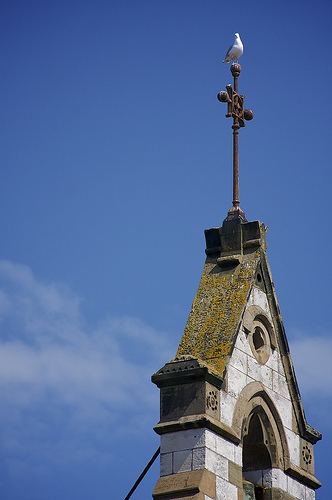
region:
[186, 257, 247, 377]
Moss covering the roof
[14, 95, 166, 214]
A cloudless blue sky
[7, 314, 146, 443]
Thin white clouds in the sky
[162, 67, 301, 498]
An old stone building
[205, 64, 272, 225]
A weather vane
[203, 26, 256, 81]
Bird on the weather vane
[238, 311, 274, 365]
Open window on the buillding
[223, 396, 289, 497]
A small archway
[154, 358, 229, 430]
Brown section of the building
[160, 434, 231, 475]
Grey stones on the arch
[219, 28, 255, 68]
small white bird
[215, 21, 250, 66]
bird sitting on top of pole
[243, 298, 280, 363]
circular window opening in wall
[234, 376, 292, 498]
brick arch in wall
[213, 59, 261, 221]
metal pole on top of wall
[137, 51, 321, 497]
triangular wall at top of tower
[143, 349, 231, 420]
decorative pieces on side of wall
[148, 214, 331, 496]
grey brick and mortar wall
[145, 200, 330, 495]
wall with metal adornments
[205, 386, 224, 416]
decorative hole pattern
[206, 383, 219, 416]
DECORATED BLOCK ON BUILDING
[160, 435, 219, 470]
WHITE STONE BLOCKS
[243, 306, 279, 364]
CIRCULAR OPENING ON BUILDING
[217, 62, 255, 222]
OLD METAL CHURCH CROSS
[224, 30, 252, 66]
GREY AND WHITE PERCHED PIGEON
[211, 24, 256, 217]
PEGION PERCHED ON TOP OF CHRUCH CROSS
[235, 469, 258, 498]
OLD BELL HANGING IN CHURCH BELL TOWER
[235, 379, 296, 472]
CONCRETE ARCHWAY IN BELL TOWER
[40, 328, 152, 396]
WHITE CLOUDS IN BLUE SKY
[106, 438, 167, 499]
METAL BRACE TO BRACE BELL TOWER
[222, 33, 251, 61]
white bird on church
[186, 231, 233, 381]
church has orange roof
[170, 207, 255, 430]
roof shows signs of rust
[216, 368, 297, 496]
arched opening in roof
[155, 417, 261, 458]
white bricks in roof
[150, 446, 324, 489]
brown bricks in roof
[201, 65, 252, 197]
rusty brown crucifix on building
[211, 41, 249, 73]
bird has blue feathers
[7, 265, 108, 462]
sky is blue with clouds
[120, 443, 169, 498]
rail behind church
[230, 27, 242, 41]
the head of a bird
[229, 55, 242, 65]
the legs of a bird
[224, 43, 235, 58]
the wing of a bird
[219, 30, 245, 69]
a bird on the pole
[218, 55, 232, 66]
the tail of a bird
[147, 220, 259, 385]
the roof of a building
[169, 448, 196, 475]
a stone in the wall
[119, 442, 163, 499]
a black metal pole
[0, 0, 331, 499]
a clear blue sky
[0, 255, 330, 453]
a white cloud